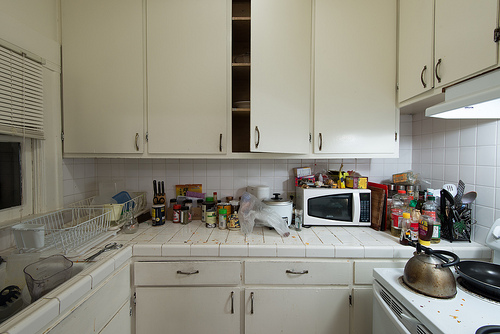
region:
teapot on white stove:
[392, 219, 470, 313]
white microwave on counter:
[287, 171, 390, 235]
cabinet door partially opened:
[193, 11, 302, 168]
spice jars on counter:
[147, 191, 247, 237]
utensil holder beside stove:
[437, 173, 482, 249]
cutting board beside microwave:
[368, 176, 400, 244]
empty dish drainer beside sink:
[17, 194, 123, 254]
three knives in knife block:
[137, 171, 175, 226]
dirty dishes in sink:
[6, 248, 77, 316]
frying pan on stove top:
[457, 245, 498, 305]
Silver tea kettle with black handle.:
[398, 242, 468, 318]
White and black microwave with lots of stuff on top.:
[292, 160, 375, 234]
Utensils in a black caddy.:
[436, 174, 480, 245]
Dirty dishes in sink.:
[0, 252, 90, 320]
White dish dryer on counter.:
[10, 195, 137, 251]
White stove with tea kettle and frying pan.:
[360, 218, 498, 332]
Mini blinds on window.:
[1, 39, 58, 136]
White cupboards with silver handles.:
[136, 261, 339, 331]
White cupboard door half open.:
[182, 4, 282, 164]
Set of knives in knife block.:
[147, 174, 169, 205]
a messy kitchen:
[10, 27, 484, 325]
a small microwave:
[299, 183, 378, 231]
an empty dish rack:
[13, 197, 115, 255]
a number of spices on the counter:
[147, 195, 244, 236]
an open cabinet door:
[223, 9, 323, 161]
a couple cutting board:
[361, 175, 393, 233]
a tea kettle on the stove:
[397, 232, 477, 317]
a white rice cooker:
[264, 187, 299, 233]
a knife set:
[148, 177, 172, 217]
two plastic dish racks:
[16, 185, 159, 249]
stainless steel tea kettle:
[398, 244, 455, 298]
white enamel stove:
[373, 219, 498, 331]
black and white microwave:
[300, 186, 373, 228]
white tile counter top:
[3, 206, 482, 331]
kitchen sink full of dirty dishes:
[1, 251, 93, 331]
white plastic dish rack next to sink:
[8, 198, 121, 258]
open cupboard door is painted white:
[225, 1, 310, 157]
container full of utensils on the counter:
[438, 179, 477, 240]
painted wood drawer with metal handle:
[133, 257, 240, 285]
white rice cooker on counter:
[263, 191, 293, 231]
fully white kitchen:
[4, 1, 496, 326]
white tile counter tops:
[4, 192, 496, 328]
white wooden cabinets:
[61, 4, 498, 330]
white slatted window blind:
[0, 40, 52, 145]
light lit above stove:
[371, 68, 499, 331]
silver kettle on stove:
[371, 217, 498, 329]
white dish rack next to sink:
[15, 205, 119, 260]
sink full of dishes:
[5, 245, 84, 320]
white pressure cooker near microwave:
[258, 190, 296, 235]